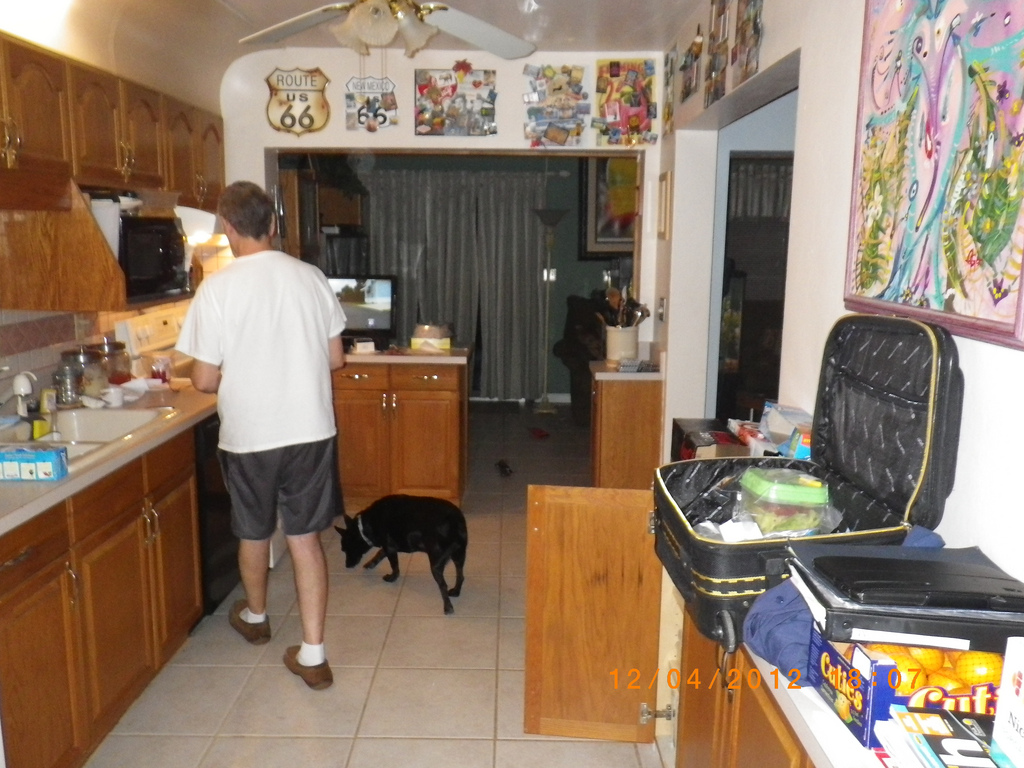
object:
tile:
[345, 737, 495, 768]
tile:
[377, 616, 498, 670]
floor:
[77, 401, 669, 768]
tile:
[254, 614, 393, 667]